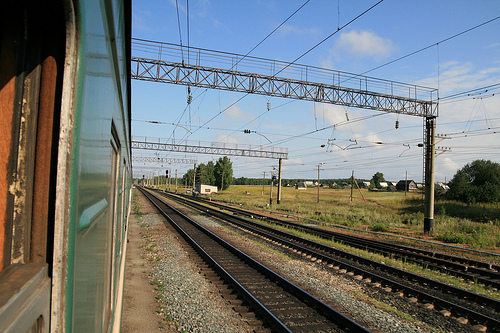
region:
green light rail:
[30, 11, 154, 323]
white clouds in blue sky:
[319, 13, 364, 49]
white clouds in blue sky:
[387, 33, 427, 62]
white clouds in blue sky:
[426, 58, 476, 94]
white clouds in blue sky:
[454, 120, 478, 154]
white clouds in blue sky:
[269, 108, 298, 133]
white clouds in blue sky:
[309, 135, 341, 160]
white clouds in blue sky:
[342, 105, 387, 143]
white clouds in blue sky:
[206, 98, 225, 109]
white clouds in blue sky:
[148, 105, 185, 130]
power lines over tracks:
[150, 25, 498, 160]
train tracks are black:
[151, 208, 461, 327]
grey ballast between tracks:
[168, 224, 438, 331]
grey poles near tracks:
[397, 76, 466, 236]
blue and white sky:
[382, 30, 454, 95]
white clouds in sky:
[383, 32, 488, 154]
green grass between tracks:
[219, 164, 429, 258]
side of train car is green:
[15, 94, 118, 306]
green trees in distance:
[176, 160, 229, 178]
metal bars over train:
[140, 49, 390, 135]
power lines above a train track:
[150, 6, 492, 108]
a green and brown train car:
[12, 9, 136, 329]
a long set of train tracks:
[139, 180, 498, 330]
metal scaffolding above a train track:
[143, 50, 441, 112]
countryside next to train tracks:
[238, 169, 468, 238]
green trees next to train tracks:
[192, 160, 235, 186]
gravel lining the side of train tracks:
[146, 218, 180, 314]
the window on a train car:
[95, 122, 126, 320]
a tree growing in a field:
[452, 166, 495, 206]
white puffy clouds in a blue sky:
[338, 30, 391, 61]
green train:
[61, 28, 143, 313]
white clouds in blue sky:
[302, 19, 348, 54]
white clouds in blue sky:
[339, 38, 399, 75]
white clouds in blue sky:
[296, 103, 330, 139]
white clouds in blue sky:
[344, 133, 385, 157]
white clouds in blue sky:
[279, 145, 325, 192]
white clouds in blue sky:
[247, 137, 289, 171]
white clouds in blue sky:
[154, 103, 199, 121]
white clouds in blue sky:
[443, 62, 494, 109]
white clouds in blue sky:
[439, 99, 469, 119]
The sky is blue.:
[201, 5, 255, 40]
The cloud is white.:
[343, 30, 392, 56]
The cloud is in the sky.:
[344, 28, 394, 55]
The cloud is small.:
[341, 27, 396, 59]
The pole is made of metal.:
[423, 117, 439, 232]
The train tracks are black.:
[171, 219, 276, 293]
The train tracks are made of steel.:
[186, 237, 294, 297]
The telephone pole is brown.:
[312, 162, 327, 204]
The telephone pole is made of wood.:
[312, 162, 324, 203]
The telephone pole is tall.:
[313, 162, 325, 205]